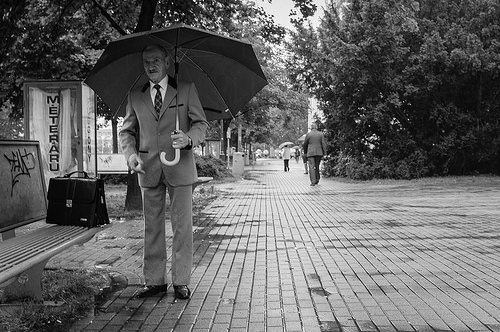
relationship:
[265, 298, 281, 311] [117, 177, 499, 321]
brick in sidewalk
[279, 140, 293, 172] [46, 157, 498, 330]
person walking on sidewalk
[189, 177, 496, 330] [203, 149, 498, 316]
brick in sidewalk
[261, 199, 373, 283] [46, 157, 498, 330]
wet brick on sidewalk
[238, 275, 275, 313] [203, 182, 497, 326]
wet brick in sidewalk